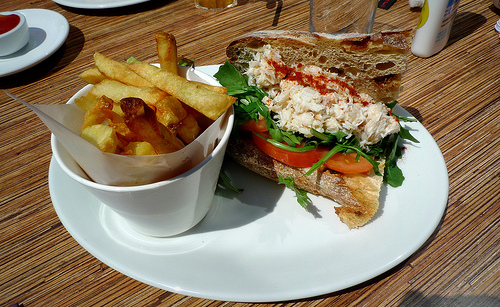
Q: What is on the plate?
A: Sandwich and fries.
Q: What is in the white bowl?
A: French fries.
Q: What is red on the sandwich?
A: Tomato.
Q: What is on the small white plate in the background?
A: Ketchup.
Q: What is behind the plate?
A: A glass.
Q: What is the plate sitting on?
A: A table.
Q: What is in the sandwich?
A: Fillings.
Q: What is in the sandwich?
A: Lettuce.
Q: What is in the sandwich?
A: Tomatoes.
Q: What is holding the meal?
A: A white plate.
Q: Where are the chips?
A: In a cup.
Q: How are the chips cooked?
A: They are fried.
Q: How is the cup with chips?
A: It is white.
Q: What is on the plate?
A: Lunch.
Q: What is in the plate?
A: A sandwich and fries.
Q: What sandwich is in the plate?
A: Chicken salad sandwich.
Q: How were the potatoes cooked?
A: Fried.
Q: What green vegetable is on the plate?
A: Lettuce.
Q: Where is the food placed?
A: On a plate.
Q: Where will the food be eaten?
A: At the table.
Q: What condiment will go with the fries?
A: Ketchup.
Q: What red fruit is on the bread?
A: Tomato.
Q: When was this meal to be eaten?
A: Either lunch or dinner.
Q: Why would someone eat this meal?
A: They were hungry.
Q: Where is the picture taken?
A: At the table.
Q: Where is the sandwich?
A: On a plate.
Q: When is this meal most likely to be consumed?
A: Lunch.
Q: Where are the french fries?
A: In a cup.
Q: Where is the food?
A: On the plate.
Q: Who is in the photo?
A: No one.